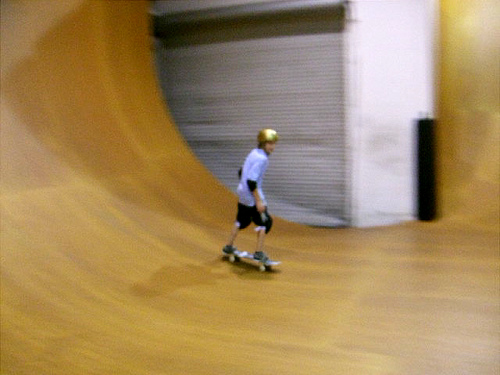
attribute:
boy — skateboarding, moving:
[217, 120, 292, 273]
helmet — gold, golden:
[248, 122, 281, 150]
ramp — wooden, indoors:
[3, 0, 495, 364]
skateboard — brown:
[220, 244, 283, 276]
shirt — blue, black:
[228, 146, 278, 209]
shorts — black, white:
[228, 202, 276, 234]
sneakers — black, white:
[221, 245, 275, 265]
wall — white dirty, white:
[159, 8, 447, 218]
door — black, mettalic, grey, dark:
[410, 110, 445, 224]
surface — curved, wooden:
[12, 185, 472, 366]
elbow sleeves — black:
[231, 164, 260, 194]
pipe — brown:
[154, 2, 349, 51]